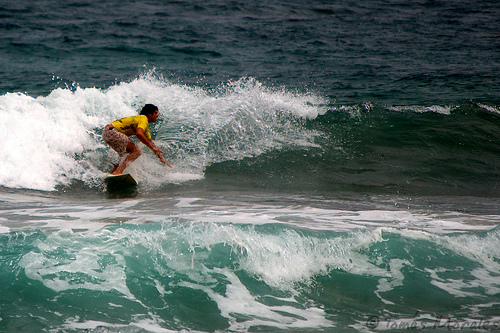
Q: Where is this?
A: This is at the ocean.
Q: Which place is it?
A: It is an ocean.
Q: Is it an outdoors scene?
A: Yes, it is outdoors.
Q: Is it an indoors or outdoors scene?
A: It is outdoors.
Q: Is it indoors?
A: No, it is outdoors.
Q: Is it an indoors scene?
A: No, it is outdoors.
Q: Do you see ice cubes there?
A: No, there are no ice cubes.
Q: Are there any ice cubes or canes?
A: No, there are no ice cubes or canes.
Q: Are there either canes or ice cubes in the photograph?
A: No, there are no ice cubes or canes.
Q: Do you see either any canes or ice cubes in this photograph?
A: No, there are no ice cubes or canes.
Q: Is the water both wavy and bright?
A: Yes, the water is wavy and bright.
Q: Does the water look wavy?
A: Yes, the water is wavy.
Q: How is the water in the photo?
A: The water is wavy.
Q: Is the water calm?
A: No, the water is wavy.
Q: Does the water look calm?
A: No, the water is wavy.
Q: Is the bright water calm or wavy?
A: The water is wavy.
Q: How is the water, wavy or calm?
A: The water is wavy.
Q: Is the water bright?
A: Yes, the water is bright.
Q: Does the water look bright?
A: Yes, the water is bright.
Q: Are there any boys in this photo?
A: No, there are no boys.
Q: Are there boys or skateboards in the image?
A: No, there are no boys or skateboards.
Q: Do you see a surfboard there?
A: Yes, there is a surfboard.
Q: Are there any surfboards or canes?
A: Yes, there is a surfboard.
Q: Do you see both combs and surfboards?
A: No, there is a surfboard but no combs.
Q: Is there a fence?
A: No, there are no fences.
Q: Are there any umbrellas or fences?
A: No, there are no fences or umbrellas.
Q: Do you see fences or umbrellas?
A: No, there are no fences or umbrellas.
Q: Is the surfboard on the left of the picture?
A: Yes, the surfboard is on the left of the image.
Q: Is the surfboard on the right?
A: No, the surfboard is on the left of the image.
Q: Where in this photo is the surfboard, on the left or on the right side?
A: The surfboard is on the left of the image.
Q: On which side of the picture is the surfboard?
A: The surfboard is on the left of the image.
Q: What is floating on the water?
A: The surfboard is floating on the water.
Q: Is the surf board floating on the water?
A: Yes, the surf board is floating on the water.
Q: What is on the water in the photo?
A: The surf board is on the water.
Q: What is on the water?
A: The surf board is on the water.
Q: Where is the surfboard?
A: The surfboard is on the water.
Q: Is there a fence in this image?
A: No, there are no fences.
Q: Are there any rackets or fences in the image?
A: No, there are no fences or rackets.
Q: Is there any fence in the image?
A: No, there are no fences.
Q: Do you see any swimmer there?
A: Yes, there is a swimmer.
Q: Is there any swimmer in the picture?
A: Yes, there is a swimmer.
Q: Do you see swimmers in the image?
A: Yes, there is a swimmer.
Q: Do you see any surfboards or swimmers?
A: Yes, there is a swimmer.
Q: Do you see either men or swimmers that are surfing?
A: Yes, the swimmer is surfing.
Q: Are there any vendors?
A: No, there are no vendors.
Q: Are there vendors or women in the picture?
A: No, there are no vendors or women.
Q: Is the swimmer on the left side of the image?
A: Yes, the swimmer is on the left of the image.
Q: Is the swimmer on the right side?
A: No, the swimmer is on the left of the image.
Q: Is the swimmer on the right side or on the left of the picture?
A: The swimmer is on the left of the image.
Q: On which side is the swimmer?
A: The swimmer is on the left of the image.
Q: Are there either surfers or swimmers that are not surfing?
A: No, there is a swimmer but he is surfing.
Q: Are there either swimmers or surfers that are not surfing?
A: No, there is a swimmer but he is surfing.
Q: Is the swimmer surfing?
A: Yes, the swimmer is surfing.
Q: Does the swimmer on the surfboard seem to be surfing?
A: Yes, the swimmer is surfing.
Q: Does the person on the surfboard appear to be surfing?
A: Yes, the swimmer is surfing.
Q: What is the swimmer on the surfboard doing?
A: The swimmer is surfing.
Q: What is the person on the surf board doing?
A: The swimmer is surfing.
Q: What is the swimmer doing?
A: The swimmer is surfing.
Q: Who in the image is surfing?
A: The swimmer is surfing.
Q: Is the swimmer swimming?
A: No, the swimmer is surfing.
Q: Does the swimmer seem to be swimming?
A: No, the swimmer is surfing.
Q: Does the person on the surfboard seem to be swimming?
A: No, the swimmer is surfing.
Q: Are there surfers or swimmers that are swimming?
A: No, there is a swimmer but he is surfing.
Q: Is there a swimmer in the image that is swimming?
A: No, there is a swimmer but he is surfing.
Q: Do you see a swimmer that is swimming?
A: No, there is a swimmer but he is surfing.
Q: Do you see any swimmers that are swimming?
A: No, there is a swimmer but he is surfing.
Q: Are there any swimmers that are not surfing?
A: No, there is a swimmer but he is surfing.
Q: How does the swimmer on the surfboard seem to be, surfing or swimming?
A: The swimmer is surfing.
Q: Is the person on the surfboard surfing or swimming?
A: The swimmer is surfing.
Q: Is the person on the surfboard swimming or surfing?
A: The swimmer is surfing.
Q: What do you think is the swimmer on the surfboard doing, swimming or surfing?
A: The swimmer is surfing.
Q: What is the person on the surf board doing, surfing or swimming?
A: The swimmer is surfing.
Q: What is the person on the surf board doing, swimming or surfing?
A: The swimmer is surfing.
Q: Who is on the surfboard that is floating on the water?
A: The swimmer is on the surf board.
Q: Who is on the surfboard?
A: The swimmer is on the surf board.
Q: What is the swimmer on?
A: The swimmer is on the surfboard.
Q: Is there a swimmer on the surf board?
A: Yes, there is a swimmer on the surf board.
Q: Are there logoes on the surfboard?
A: No, there is a swimmer on the surfboard.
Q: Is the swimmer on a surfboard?
A: Yes, the swimmer is on a surfboard.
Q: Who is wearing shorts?
A: The swimmer is wearing shorts.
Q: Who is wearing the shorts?
A: The swimmer is wearing shorts.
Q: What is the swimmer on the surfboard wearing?
A: The swimmer is wearing shorts.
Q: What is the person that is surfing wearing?
A: The swimmer is wearing shorts.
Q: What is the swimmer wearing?
A: The swimmer is wearing shorts.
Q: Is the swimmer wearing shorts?
A: Yes, the swimmer is wearing shorts.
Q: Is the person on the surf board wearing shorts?
A: Yes, the swimmer is wearing shorts.